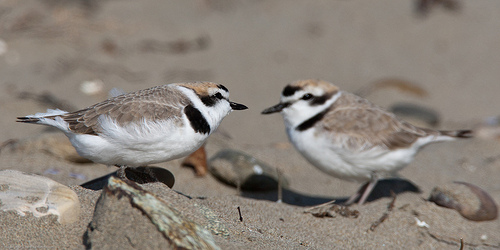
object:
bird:
[260, 79, 477, 206]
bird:
[11, 81, 250, 187]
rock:
[210, 141, 282, 191]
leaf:
[117, 185, 199, 245]